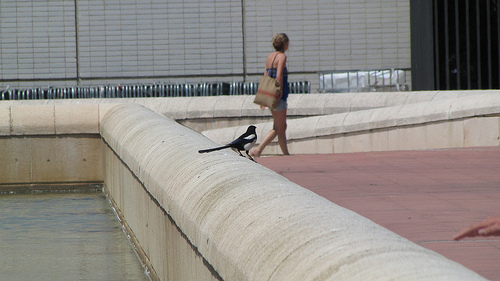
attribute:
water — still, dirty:
[6, 174, 162, 279]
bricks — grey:
[7, 2, 81, 78]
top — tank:
[265, 68, 272, 78]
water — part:
[46, 195, 95, 247]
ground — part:
[334, 156, 392, 196]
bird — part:
[205, 122, 261, 163]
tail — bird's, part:
[191, 136, 228, 164]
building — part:
[128, 8, 225, 79]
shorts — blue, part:
[277, 101, 283, 112]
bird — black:
[199, 122, 264, 162]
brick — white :
[78, 69, 92, 76]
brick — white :
[105, 67, 120, 78]